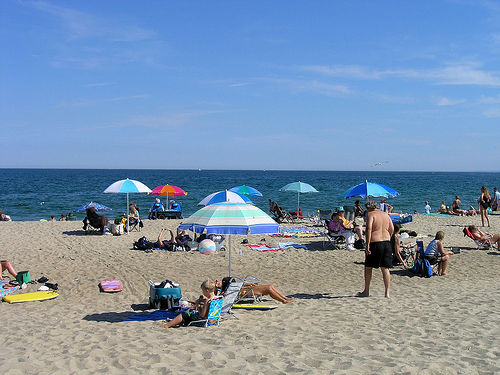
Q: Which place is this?
A: It is a beach.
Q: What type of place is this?
A: It is a beach.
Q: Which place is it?
A: It is a beach.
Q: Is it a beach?
A: Yes, it is a beach.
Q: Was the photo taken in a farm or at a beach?
A: It was taken at a beach.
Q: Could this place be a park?
A: No, it is a beach.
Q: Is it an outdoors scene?
A: Yes, it is outdoors.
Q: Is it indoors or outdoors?
A: It is outdoors.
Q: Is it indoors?
A: No, it is outdoors.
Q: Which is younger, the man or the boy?
A: The boy is younger than the man.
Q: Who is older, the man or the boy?
A: The man is older than the boy.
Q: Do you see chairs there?
A: Yes, there is a chair.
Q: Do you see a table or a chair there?
A: Yes, there is a chair.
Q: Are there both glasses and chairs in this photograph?
A: No, there is a chair but no glasses.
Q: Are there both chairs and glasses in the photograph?
A: No, there is a chair but no glasses.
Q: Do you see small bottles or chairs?
A: Yes, there is a small chair.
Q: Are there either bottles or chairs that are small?
A: Yes, the chair is small.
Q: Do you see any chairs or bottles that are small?
A: Yes, the chair is small.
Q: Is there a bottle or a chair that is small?
A: Yes, the chair is small.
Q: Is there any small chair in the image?
A: Yes, there is a small chair.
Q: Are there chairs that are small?
A: Yes, there is a chair that is small.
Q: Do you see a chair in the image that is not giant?
A: Yes, there is a small chair.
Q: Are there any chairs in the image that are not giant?
A: Yes, there is a small chair.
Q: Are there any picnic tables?
A: No, there are no picnic tables.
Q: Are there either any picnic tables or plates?
A: No, there are no picnic tables or plates.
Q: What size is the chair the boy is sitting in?
A: The chair is small.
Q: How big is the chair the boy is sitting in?
A: The chair is small.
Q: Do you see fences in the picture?
A: No, there are no fences.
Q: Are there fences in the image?
A: No, there are no fences.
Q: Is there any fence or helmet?
A: No, there are no fences or helmets.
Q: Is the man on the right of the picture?
A: Yes, the man is on the right of the image.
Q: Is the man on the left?
A: No, the man is on the right of the image.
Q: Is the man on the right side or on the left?
A: The man is on the right of the image.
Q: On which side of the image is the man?
A: The man is on the right of the image.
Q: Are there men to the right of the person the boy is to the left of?
A: Yes, there is a man to the right of the person.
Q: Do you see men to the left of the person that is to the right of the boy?
A: No, the man is to the right of the person.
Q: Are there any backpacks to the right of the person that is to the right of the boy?
A: No, there is a man to the right of the person.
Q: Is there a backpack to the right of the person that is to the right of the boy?
A: No, there is a man to the right of the person.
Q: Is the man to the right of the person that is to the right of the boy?
A: Yes, the man is to the right of the person.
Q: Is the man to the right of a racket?
A: No, the man is to the right of the person.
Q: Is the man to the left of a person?
A: No, the man is to the right of a person.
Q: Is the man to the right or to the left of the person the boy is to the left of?
A: The man is to the right of the person.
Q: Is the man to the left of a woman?
A: Yes, the man is to the left of a woman.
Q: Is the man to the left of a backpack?
A: No, the man is to the left of a woman.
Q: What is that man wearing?
A: The man is wearing shorts.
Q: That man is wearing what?
A: The man is wearing shorts.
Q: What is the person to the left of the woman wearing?
A: The man is wearing shorts.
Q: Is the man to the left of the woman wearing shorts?
A: Yes, the man is wearing shorts.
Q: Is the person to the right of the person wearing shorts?
A: Yes, the man is wearing shorts.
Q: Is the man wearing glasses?
A: No, the man is wearing shorts.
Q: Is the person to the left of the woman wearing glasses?
A: No, the man is wearing shorts.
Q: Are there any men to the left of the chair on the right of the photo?
A: Yes, there is a man to the left of the chair.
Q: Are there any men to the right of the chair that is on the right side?
A: No, the man is to the left of the chair.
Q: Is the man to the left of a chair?
A: Yes, the man is to the left of a chair.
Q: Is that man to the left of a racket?
A: No, the man is to the left of a chair.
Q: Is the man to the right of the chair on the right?
A: No, the man is to the left of the chair.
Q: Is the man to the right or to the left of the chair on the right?
A: The man is to the left of the chair.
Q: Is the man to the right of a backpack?
A: No, the man is to the right of the umbrella.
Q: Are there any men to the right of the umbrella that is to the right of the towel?
A: Yes, there is a man to the right of the umbrella.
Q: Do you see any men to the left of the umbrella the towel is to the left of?
A: No, the man is to the right of the umbrella.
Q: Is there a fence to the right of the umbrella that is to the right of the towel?
A: No, there is a man to the right of the umbrella.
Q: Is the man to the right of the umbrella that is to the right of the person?
A: Yes, the man is to the right of the umbrella.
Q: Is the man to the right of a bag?
A: No, the man is to the right of the umbrella.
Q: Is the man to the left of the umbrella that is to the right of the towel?
A: No, the man is to the right of the umbrella.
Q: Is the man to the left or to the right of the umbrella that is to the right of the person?
A: The man is to the right of the umbrella.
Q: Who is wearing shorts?
A: The man is wearing shorts.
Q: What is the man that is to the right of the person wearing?
A: The man is wearing shorts.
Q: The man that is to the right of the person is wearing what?
A: The man is wearing shorts.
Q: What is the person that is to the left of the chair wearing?
A: The man is wearing shorts.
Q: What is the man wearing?
A: The man is wearing shorts.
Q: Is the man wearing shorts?
A: Yes, the man is wearing shorts.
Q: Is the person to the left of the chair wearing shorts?
A: Yes, the man is wearing shorts.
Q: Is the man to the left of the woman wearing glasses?
A: No, the man is wearing shorts.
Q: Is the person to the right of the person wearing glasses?
A: No, the man is wearing shorts.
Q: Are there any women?
A: Yes, there is a woman.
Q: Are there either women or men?
A: Yes, there is a woman.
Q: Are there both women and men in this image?
A: Yes, there are both a woman and a man.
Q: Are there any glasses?
A: No, there are no glasses.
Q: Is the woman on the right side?
A: Yes, the woman is on the right of the image.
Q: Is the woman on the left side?
A: No, the woman is on the right of the image.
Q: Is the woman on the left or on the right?
A: The woman is on the right of the image.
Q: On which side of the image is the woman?
A: The woman is on the right of the image.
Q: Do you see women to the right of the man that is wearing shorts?
A: Yes, there is a woman to the right of the man.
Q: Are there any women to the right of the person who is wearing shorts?
A: Yes, there is a woman to the right of the man.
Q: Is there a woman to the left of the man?
A: No, the woman is to the right of the man.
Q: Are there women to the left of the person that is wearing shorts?
A: No, the woman is to the right of the man.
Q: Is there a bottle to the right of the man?
A: No, there is a woman to the right of the man.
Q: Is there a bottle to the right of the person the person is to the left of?
A: No, there is a woman to the right of the man.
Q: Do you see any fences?
A: No, there are no fences.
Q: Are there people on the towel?
A: Yes, there is a person on the towel.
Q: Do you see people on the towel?
A: Yes, there is a person on the towel.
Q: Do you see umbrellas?
A: Yes, there is an umbrella.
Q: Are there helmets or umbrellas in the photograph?
A: Yes, there is an umbrella.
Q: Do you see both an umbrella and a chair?
A: Yes, there are both an umbrella and a chair.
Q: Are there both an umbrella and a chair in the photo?
A: Yes, there are both an umbrella and a chair.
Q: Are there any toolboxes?
A: No, there are no toolboxes.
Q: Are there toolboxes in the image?
A: No, there are no toolboxes.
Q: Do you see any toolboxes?
A: No, there are no toolboxes.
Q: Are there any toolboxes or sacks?
A: No, there are no toolboxes or sacks.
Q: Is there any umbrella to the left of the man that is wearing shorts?
A: Yes, there is an umbrella to the left of the man.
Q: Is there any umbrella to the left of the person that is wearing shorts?
A: Yes, there is an umbrella to the left of the man.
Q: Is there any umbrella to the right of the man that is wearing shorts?
A: No, the umbrella is to the left of the man.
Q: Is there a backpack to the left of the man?
A: No, there is an umbrella to the left of the man.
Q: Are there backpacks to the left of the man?
A: No, there is an umbrella to the left of the man.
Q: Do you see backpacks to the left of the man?
A: No, there is an umbrella to the left of the man.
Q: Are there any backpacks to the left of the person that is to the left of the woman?
A: No, there is an umbrella to the left of the man.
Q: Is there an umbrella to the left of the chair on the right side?
A: Yes, there is an umbrella to the left of the chair.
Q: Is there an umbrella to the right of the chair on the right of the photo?
A: No, the umbrella is to the left of the chair.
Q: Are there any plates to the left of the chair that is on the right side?
A: No, there is an umbrella to the left of the chair.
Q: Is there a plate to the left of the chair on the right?
A: No, there is an umbrella to the left of the chair.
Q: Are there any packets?
A: No, there are no packets.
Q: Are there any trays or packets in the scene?
A: No, there are no packets or trays.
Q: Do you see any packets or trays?
A: No, there are no packets or trays.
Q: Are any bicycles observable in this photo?
A: No, there are no bicycles.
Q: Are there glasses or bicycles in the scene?
A: No, there are no bicycles or glasses.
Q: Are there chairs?
A: Yes, there is a chair.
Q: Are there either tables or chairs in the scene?
A: Yes, there is a chair.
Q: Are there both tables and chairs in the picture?
A: No, there is a chair but no tables.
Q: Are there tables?
A: No, there are no tables.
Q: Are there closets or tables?
A: No, there are no tables or closets.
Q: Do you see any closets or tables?
A: No, there are no tables or closets.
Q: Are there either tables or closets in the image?
A: No, there are no tables or closets.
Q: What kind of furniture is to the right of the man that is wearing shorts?
A: The piece of furniture is a chair.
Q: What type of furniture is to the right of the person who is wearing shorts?
A: The piece of furniture is a chair.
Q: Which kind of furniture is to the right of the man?
A: The piece of furniture is a chair.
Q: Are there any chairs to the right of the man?
A: Yes, there is a chair to the right of the man.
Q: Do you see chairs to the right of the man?
A: Yes, there is a chair to the right of the man.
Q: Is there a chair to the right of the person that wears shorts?
A: Yes, there is a chair to the right of the man.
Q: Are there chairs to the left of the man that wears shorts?
A: No, the chair is to the right of the man.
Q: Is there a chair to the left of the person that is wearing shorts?
A: No, the chair is to the right of the man.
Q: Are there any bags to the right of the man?
A: No, there is a chair to the right of the man.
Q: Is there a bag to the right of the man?
A: No, there is a chair to the right of the man.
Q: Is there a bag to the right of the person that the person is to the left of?
A: No, there is a chair to the right of the man.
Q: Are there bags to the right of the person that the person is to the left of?
A: No, there is a chair to the right of the man.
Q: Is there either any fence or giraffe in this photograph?
A: No, there are no fences or giraffes.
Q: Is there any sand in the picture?
A: Yes, there is sand.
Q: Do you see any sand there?
A: Yes, there is sand.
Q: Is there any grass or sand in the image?
A: Yes, there is sand.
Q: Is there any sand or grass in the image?
A: Yes, there is sand.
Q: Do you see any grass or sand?
A: Yes, there is sand.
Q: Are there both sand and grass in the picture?
A: No, there is sand but no grass.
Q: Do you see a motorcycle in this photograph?
A: No, there are no motorcycles.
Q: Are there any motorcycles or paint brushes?
A: No, there are no motorcycles or paint brushes.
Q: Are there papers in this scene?
A: No, there are no papers.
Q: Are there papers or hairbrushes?
A: No, there are no papers or hairbrushes.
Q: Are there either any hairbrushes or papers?
A: No, there are no papers or hairbrushes.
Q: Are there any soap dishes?
A: No, there are no soap dishes.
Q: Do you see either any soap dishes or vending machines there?
A: No, there are no soap dishes or vending machines.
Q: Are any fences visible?
A: No, there are no fences.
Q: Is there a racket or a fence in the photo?
A: No, there are no fences or rackets.